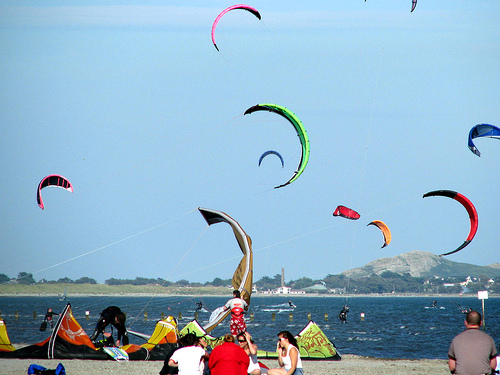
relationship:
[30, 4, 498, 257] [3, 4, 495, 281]
kites on air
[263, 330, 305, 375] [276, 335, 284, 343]
people wearing sunglasses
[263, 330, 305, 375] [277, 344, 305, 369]
people with white tank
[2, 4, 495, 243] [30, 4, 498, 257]
sky filled with kites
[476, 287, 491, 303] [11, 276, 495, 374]
sign on beach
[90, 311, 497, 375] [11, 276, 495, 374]
people sitting on beach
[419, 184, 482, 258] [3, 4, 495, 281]
kite in air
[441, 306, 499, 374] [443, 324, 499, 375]
man wearing gray shirt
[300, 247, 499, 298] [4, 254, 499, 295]
hill in distance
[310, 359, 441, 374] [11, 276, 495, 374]
sand on beach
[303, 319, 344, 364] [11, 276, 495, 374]
kite laying on beach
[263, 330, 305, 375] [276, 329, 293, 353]
people seen head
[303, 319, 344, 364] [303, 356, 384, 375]
kite on ground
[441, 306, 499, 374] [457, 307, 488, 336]
man has head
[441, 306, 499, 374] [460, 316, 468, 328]
man has ear